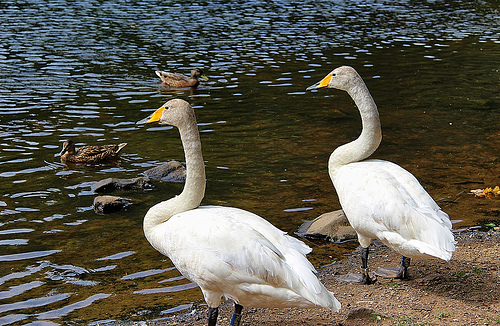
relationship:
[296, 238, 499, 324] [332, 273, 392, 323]
ground in dirt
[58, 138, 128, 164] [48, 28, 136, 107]
duck on water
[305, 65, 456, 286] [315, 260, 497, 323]
bird standing on shore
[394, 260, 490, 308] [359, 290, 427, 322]
shadow on ground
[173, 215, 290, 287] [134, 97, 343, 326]
white feathers on bird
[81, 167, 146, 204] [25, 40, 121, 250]
rocks in water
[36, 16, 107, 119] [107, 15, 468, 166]
stones out of water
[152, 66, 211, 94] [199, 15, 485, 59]
duck in water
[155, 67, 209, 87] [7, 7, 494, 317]
duck loating on water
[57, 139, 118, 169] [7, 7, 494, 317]
duck loating on water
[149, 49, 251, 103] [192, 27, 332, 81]
duck wading in water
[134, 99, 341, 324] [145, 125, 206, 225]
bird has a neck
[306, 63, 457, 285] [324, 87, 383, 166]
bird has a neck